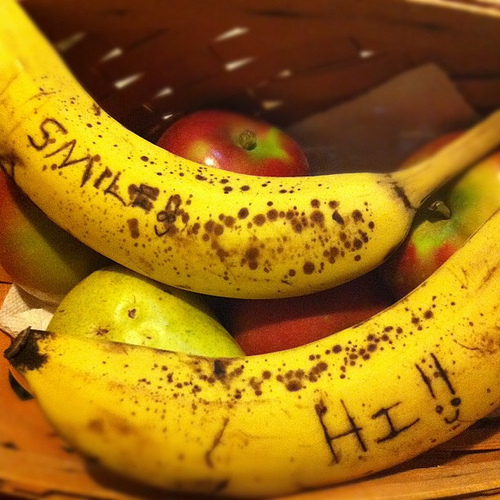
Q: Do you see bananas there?
A: Yes, there is a banana.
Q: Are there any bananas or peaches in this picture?
A: Yes, there is a banana.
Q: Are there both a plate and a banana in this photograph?
A: No, there is a banana but no plates.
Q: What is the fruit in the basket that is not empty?
A: The fruit is a banana.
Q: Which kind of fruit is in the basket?
A: The fruit is a banana.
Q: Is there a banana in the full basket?
A: Yes, there is a banana in the basket.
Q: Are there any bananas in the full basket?
A: Yes, there is a banana in the basket.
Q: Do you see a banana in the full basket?
A: Yes, there is a banana in the basket.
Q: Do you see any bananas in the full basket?
A: Yes, there is a banana in the basket.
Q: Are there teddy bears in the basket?
A: No, there is a banana in the basket.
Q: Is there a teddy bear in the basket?
A: No, there is a banana in the basket.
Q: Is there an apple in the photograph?
A: Yes, there is an apple.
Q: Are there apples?
A: Yes, there is an apple.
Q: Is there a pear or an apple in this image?
A: Yes, there is an apple.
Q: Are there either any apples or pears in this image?
A: Yes, there is an apple.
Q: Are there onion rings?
A: No, there are no onion rings.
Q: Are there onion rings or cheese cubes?
A: No, there are no onion rings or cheese cubes.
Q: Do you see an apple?
A: Yes, there is an apple.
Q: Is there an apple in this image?
A: Yes, there is an apple.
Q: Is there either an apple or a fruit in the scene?
A: Yes, there is an apple.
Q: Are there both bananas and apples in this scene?
A: Yes, there are both an apple and bananas.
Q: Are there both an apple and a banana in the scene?
A: Yes, there are both an apple and a banana.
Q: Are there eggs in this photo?
A: No, there are no eggs.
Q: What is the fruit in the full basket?
A: The fruit is an apple.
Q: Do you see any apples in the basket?
A: Yes, there is an apple in the basket.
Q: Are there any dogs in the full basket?
A: No, there is an apple in the basket.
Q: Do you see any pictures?
A: No, there are no pictures.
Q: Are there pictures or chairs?
A: No, there are no pictures or chairs.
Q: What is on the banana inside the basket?
A: The drawing is on the banana.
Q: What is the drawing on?
A: The drawing is on the banana.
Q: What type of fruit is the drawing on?
A: The drawing is on the banana.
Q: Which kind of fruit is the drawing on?
A: The drawing is on the banana.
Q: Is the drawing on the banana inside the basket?
A: Yes, the drawing is on the banana.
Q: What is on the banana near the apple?
A: The drawing is on the banana.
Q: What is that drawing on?
A: The drawing is on the banana.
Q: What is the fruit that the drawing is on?
A: The fruit is a banana.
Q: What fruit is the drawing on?
A: The drawing is on the banana.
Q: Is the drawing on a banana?
A: Yes, the drawing is on a banana.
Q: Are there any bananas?
A: Yes, there is a banana.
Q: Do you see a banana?
A: Yes, there is a banana.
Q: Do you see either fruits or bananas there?
A: Yes, there is a banana.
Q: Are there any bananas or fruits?
A: Yes, there is a banana.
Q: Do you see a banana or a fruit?
A: Yes, there is a banana.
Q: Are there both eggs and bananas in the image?
A: No, there is a banana but no eggs.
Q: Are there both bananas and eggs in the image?
A: No, there is a banana but no eggs.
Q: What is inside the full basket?
A: The banana is inside the basket.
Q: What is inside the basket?
A: The banana is inside the basket.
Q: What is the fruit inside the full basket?
A: The fruit is a banana.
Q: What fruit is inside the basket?
A: The fruit is a banana.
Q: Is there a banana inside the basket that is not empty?
A: Yes, there is a banana inside the basket.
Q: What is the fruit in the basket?
A: The fruit is a banana.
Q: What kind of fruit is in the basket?
A: The fruit is a banana.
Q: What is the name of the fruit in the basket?
A: The fruit is a banana.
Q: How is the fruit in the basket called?
A: The fruit is a banana.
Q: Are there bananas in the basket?
A: Yes, there is a banana in the basket.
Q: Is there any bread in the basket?
A: No, there is a banana in the basket.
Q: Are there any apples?
A: Yes, there is an apple.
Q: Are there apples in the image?
A: Yes, there is an apple.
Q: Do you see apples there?
A: Yes, there is an apple.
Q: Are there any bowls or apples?
A: Yes, there is an apple.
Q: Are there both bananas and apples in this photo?
A: Yes, there are both an apple and bananas.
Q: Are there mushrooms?
A: No, there are no mushrooms.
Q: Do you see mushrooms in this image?
A: No, there are no mushrooms.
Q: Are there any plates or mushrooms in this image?
A: No, there are no mushrooms or plates.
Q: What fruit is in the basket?
A: The fruit is an apple.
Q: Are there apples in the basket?
A: Yes, there is an apple in the basket.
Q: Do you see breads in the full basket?
A: No, there is an apple in the basket.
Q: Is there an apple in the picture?
A: Yes, there is an apple.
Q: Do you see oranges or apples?
A: Yes, there is an apple.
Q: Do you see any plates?
A: No, there are no plates.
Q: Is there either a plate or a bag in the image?
A: No, there are no plates or bags.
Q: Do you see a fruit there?
A: Yes, there is a fruit.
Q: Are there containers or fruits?
A: Yes, there is a fruit.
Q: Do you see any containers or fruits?
A: Yes, there is a fruit.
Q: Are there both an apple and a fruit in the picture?
A: Yes, there are both a fruit and an apple.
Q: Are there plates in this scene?
A: No, there are no plates.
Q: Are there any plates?
A: No, there are no plates.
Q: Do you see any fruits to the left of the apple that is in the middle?
A: Yes, there is a fruit to the left of the apple.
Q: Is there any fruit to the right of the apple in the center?
A: No, the fruit is to the left of the apple.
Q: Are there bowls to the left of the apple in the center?
A: No, there is a fruit to the left of the apple.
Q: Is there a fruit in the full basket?
A: Yes, there is a fruit in the basket.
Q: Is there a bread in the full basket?
A: No, there is a fruit in the basket.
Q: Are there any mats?
A: No, there are no mats.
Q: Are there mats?
A: No, there are no mats.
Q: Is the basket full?
A: Yes, the basket is full.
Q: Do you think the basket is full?
A: Yes, the basket is full.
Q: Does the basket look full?
A: Yes, the basket is full.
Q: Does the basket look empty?
A: No, the basket is full.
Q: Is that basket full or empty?
A: The basket is full.